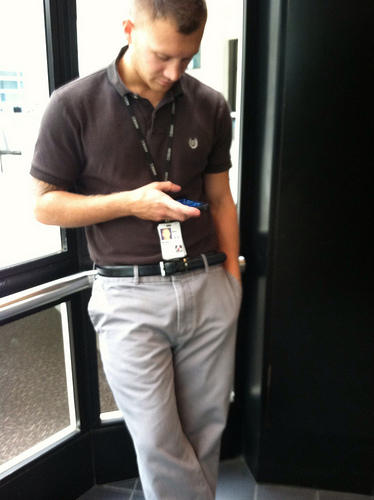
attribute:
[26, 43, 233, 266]
shirt —  grey polo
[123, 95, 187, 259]
badge — hanging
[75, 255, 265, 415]
pants — khaki, Pair 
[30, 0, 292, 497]
man standing — standing inside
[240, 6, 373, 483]
walls — black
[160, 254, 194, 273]
buckle — silver, black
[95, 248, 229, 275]
belt — narrow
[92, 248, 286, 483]
pants — khaki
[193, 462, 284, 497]
floor — dark grey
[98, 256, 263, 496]
slacks — grey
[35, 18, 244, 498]
boy — dark grey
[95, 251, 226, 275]
belt — black, leather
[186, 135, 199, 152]
white logo — black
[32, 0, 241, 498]
man — standing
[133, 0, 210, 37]
hair — short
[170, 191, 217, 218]
cellphone — blue, black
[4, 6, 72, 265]
window pane — glass